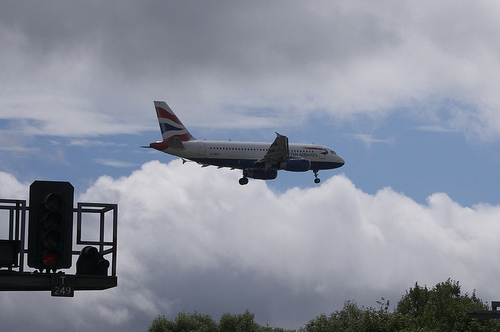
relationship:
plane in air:
[150, 100, 345, 186] [3, 4, 500, 309]